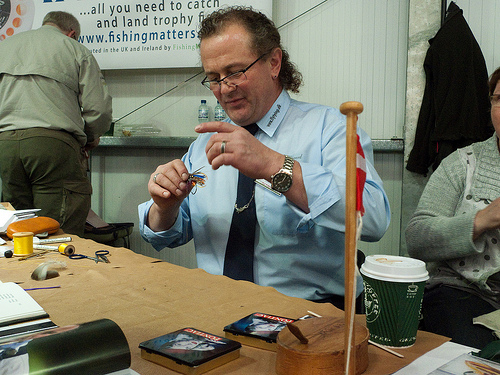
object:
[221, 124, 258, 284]
tie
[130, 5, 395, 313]
man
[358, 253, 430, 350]
cup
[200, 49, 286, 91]
glasses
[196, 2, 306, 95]
hair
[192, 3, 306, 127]
head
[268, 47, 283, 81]
ear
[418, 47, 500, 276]
person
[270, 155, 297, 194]
watch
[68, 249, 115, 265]
scissors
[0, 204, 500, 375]
table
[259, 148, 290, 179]
wrist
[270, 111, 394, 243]
arm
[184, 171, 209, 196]
bait